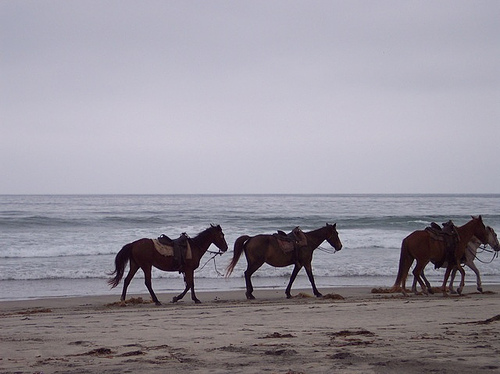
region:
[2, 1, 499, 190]
Sky at the beach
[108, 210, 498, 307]
A pack of four horses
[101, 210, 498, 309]
Four horses running on the beach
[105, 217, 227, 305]
A brown horse with a saddle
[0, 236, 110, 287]
waves crashing into the beach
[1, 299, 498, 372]
Beach sand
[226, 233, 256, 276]
A brown horse's tail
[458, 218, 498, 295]
A white horse on the beach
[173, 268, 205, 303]
A pair of brown legs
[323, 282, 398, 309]
Pieces of seaweed on the beach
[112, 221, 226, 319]
A brown horse walking on the beach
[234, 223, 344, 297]
A brown horse walking on the beach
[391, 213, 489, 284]
A brown horse walking on the beach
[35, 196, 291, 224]
A still ocean waters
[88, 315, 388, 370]
Sandy beach with hoof trails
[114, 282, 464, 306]
Sandy beach with hoof trails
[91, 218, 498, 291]
Four horses walking along the beach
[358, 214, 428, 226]
An ocean wave in the water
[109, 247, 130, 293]
A beautiful horse tail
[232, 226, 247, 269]
A beautiful horse tail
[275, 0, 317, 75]
part of a cloud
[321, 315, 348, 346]
part of a beach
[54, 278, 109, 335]
edge of a shore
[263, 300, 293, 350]
part of a sand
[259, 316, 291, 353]
part of a beach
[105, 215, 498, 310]
the horses on the beach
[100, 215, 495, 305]
the horses walking on the beach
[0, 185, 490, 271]
the large body of water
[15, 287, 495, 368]
the sand on the beach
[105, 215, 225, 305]
the horse in the back of the line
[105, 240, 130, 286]
the tail on the last horse in the line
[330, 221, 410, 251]
the white waves in the ocean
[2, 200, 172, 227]
the waves in the ocean beginning to form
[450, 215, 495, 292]
the light colored horse in the front of the line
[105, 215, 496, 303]
the four horses on the beach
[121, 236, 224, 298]
Horse on the beach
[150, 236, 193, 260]
Saddle on a horse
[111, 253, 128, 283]
Tail of a horse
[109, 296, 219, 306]
Horse footsteps on a beach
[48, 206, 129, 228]
Waves in the water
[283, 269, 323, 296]
Front legs of a horse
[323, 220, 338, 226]
Ears of a horse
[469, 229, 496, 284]
White horse in front of other horses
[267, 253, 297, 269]
Stomach of a horse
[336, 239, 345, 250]
Nose of a horse